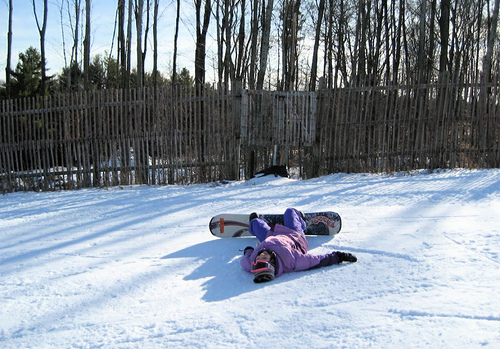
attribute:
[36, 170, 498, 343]
snow — white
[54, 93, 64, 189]
stick — wooden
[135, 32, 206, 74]
clouds — white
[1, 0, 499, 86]
sky — blue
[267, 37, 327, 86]
cloud — white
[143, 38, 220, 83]
cloud — white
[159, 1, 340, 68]
sky — blue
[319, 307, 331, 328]
snow — white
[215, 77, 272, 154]
stick — wooden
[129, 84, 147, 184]
stick — wooden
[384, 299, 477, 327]
snow — white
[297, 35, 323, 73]
clouds — white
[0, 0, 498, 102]
sky — blue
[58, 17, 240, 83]
clouds — white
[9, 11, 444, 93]
sky — blue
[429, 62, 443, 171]
stick — wooden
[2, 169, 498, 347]
hill — side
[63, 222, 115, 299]
snow — white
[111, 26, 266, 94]
clouds — white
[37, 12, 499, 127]
sky — blue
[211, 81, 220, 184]
stick — wooden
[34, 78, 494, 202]
fence — wooden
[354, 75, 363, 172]
stick — wooden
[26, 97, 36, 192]
stick — wooden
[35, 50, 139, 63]
clouds — white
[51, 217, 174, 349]
snow — white